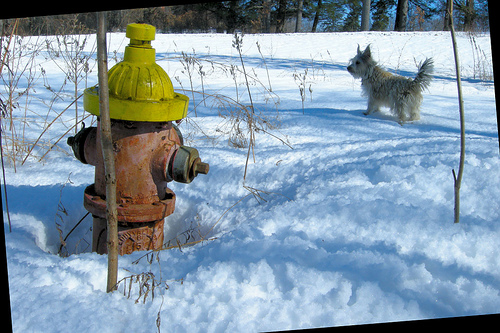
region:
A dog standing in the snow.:
[332, 45, 437, 150]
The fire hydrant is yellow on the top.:
[93, 28, 197, 120]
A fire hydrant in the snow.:
[81, 22, 188, 276]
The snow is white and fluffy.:
[251, 168, 465, 313]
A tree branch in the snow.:
[77, 16, 121, 301]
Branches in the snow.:
[183, 48, 315, 173]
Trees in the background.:
[187, 4, 482, 46]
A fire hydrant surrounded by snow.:
[61, 20, 226, 268]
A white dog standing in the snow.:
[344, 43, 437, 123]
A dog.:
[340, 39, 444, 131]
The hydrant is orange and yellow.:
[56, 18, 223, 258]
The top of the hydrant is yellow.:
[87, 23, 194, 124]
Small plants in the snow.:
[6, 28, 495, 162]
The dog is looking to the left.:
[346, 41, 436, 128]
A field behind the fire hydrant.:
[0, 26, 499, 211]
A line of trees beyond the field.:
[16, 3, 499, 44]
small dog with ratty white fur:
[340, 39, 439, 124]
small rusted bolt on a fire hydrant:
[196, 160, 211, 177]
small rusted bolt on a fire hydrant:
[65, 132, 75, 147]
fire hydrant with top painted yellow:
[56, 19, 211, 252]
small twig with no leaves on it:
[440, 0, 467, 221]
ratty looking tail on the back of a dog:
[411, 55, 436, 90]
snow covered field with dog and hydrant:
[0, 23, 495, 332]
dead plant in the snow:
[101, 267, 178, 332]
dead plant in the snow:
[125, 215, 225, 271]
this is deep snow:
[27, 18, 452, 278]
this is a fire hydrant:
[82, 40, 219, 265]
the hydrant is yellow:
[102, 11, 199, 259]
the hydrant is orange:
[67, 145, 199, 245]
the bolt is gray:
[170, 138, 227, 192]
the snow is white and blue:
[235, 150, 383, 255]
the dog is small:
[354, 44, 424, 104]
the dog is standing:
[294, 41, 485, 206]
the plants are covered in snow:
[207, 17, 338, 175]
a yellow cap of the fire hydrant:
[76, 15, 196, 125]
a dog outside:
[316, 33, 440, 131]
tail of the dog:
[406, 53, 440, 99]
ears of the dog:
[353, 41, 375, 54]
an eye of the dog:
[352, 58, 362, 67]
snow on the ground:
[224, 130, 448, 310]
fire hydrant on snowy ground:
[64, 15, 224, 300]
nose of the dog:
[344, 62, 353, 74]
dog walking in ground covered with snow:
[328, 35, 447, 133]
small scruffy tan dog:
[345, 41, 435, 123]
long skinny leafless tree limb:
[93, 11, 119, 291]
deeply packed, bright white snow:
[1, 30, 498, 331]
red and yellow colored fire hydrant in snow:
[63, 17, 207, 259]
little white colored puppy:
[332, 42, 444, 129]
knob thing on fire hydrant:
[156, 140, 216, 190]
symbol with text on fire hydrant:
[96, 219, 167, 260]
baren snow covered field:
[16, 33, 496, 317]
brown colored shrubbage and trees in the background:
[6, 4, 483, 34]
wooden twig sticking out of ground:
[436, 8, 475, 227]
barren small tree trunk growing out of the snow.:
[71, 11, 137, 301]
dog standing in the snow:
[339, 44, 441, 129]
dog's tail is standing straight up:
[389, 44, 440, 101]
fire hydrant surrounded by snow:
[66, 20, 217, 255]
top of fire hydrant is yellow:
[79, 22, 192, 122]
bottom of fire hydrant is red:
[67, 120, 212, 253]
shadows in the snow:
[278, 125, 499, 186]